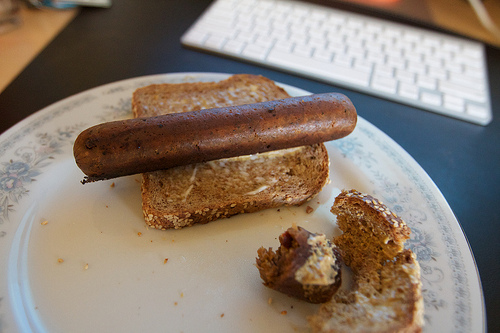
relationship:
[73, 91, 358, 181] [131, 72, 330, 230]
hot dog sitting on toast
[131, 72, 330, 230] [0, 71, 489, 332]
toast sitting on plate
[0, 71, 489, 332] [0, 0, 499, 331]
plate sitting on mat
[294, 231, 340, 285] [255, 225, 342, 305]
spread on top of hot dog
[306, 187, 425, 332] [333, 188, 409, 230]
bread has crust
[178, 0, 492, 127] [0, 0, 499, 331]
keyboard sitting on mat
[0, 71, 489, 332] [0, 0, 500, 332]
plate sitting on table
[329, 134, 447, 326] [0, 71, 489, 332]
design on top of plate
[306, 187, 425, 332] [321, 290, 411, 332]
bread has butter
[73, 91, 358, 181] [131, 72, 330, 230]
hot dog longer than toast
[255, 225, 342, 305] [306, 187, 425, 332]
hot dog sitting on bread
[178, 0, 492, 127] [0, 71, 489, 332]
keyboard in front of plate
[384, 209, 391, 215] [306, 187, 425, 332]
sesame seed on top of bread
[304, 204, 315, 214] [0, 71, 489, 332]
bread crumb sitting on plate